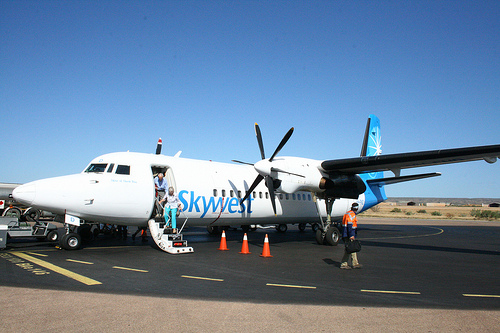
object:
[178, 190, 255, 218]
airline name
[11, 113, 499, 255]
airplane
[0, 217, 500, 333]
runway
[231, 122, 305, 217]
propeller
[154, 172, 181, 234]
passengers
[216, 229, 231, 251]
cones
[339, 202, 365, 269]
man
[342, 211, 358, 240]
orange jacket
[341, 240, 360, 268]
brown pants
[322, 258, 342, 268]
shadow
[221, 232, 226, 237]
white tips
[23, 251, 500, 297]
stripes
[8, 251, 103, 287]
yellow stripe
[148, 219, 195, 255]
ladder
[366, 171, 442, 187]
back wing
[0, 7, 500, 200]
sky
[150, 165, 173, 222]
in doorway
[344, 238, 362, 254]
black bag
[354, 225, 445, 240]
white line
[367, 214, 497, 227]
part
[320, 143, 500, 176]
wing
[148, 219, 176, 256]
side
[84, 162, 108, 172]
front windows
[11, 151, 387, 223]
airplane side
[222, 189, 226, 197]
window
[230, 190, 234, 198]
window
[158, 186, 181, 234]
woman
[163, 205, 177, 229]
green pants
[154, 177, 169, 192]
blue shirt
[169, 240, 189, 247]
steps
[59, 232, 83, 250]
front black tires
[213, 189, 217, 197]
passenger windows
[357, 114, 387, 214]
blue tail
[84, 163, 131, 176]
cockpit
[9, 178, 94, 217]
sharp nose